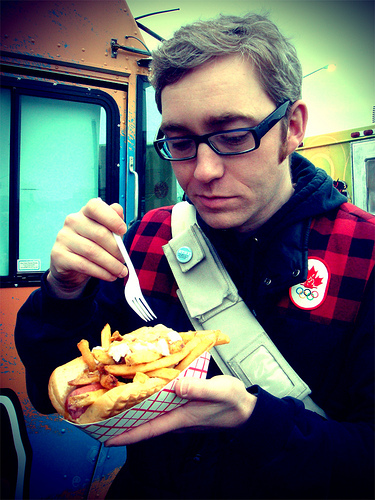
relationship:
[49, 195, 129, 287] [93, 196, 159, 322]
hand holding fork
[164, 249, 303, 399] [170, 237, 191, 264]
tan strap has blue button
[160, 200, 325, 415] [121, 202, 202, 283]
strap over shoulder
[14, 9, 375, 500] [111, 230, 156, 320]
man holding fork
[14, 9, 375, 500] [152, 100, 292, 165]
man wearing eyeglasses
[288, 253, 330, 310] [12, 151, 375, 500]
patch on coat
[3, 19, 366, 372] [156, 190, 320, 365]
man wearing backpack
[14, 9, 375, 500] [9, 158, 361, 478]
man wearing jacket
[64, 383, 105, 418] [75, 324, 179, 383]
hot dog with toppings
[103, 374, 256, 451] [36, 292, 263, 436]
hand holding food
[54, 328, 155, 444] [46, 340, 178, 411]
hot dog on bun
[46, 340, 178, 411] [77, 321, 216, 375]
bun covered with french fries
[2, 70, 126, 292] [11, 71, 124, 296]
window with frame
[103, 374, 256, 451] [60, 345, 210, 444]
hand holding tray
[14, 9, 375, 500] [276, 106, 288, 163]
man with sideburn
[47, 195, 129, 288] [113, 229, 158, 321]
hand holding fork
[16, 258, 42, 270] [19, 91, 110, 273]
sticker on a bus window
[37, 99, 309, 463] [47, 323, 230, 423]
container holds food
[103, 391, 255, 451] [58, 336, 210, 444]
hand holding container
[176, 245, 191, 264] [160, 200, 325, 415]
blue button on strap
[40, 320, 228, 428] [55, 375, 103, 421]
fries on hot dog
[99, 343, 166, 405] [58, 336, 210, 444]
food in container